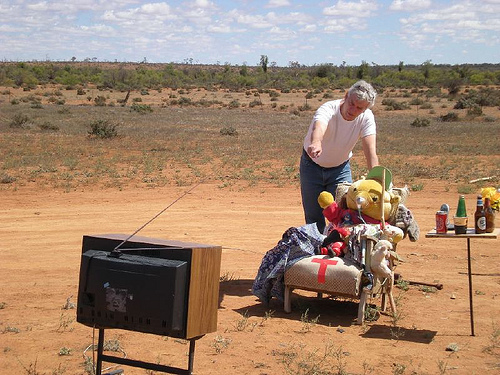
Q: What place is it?
A: It is a desert.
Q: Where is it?
A: This is at the desert.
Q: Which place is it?
A: It is a desert.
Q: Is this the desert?
A: Yes, it is the desert.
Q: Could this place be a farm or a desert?
A: It is a desert.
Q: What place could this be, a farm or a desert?
A: It is a desert.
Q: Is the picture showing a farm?
A: No, the picture is showing a desert.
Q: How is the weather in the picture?
A: It is clear.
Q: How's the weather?
A: It is clear.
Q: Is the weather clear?
A: Yes, it is clear.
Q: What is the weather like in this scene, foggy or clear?
A: It is clear.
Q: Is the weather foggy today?
A: No, it is clear.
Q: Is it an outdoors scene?
A: Yes, it is outdoors.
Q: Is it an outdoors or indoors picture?
A: It is outdoors.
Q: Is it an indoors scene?
A: No, it is outdoors.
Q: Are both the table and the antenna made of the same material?
A: No, the table is made of wood and the antenna is made of metal.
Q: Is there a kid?
A: No, there are no children.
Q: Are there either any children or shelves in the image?
A: No, there are no children or shelves.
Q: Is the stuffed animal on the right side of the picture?
A: Yes, the stuffed animal is on the right of the image.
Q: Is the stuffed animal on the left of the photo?
A: No, the stuffed animal is on the right of the image.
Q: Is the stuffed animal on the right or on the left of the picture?
A: The stuffed animal is on the right of the image.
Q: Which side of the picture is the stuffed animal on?
A: The stuffed animal is on the right of the image.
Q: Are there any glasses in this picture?
A: No, there are no glasses.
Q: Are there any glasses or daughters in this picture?
A: No, there are no glasses or daughters.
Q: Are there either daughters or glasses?
A: No, there are no glasses or daughters.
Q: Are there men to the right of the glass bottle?
A: No, the man is to the left of the bottle.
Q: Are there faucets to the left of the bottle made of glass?
A: No, there is a man to the left of the bottle.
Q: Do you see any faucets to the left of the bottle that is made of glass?
A: No, there is a man to the left of the bottle.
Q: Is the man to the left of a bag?
A: No, the man is to the left of the bottle.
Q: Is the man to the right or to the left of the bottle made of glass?
A: The man is to the left of the bottle.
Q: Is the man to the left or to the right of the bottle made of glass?
A: The man is to the left of the bottle.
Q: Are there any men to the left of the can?
A: Yes, there is a man to the left of the can.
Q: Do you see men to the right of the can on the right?
A: No, the man is to the left of the can.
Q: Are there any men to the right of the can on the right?
A: No, the man is to the left of the can.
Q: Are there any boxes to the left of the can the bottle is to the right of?
A: No, there is a man to the left of the can.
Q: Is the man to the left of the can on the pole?
A: Yes, the man is to the left of the can.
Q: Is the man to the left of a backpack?
A: No, the man is to the left of the can.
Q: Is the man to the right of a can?
A: No, the man is to the left of a can.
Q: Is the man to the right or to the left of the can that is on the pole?
A: The man is to the left of the can.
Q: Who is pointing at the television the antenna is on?
A: The man is pointing at the TV.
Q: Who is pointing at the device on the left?
A: The man is pointing at the TV.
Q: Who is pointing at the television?
A: The man is pointing at the TV.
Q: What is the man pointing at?
A: The man is pointing at the television.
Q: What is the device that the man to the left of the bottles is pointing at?
A: The device is a television.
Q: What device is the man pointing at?
A: The man is pointing at the TV.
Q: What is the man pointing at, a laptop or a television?
A: The man is pointing at a television.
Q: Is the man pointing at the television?
A: Yes, the man is pointing at the television.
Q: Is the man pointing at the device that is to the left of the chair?
A: Yes, the man is pointing at the television.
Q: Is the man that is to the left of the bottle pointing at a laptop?
A: No, the man is pointing at the television.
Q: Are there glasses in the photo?
A: No, there are no glasses.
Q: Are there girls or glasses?
A: No, there are no glasses or girls.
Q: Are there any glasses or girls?
A: No, there are no glasses or girls.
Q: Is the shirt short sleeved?
A: Yes, the shirt is short sleeved.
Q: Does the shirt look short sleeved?
A: Yes, the shirt is short sleeved.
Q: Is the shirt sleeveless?
A: No, the shirt is short sleeved.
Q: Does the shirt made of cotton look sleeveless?
A: No, the shirt is short sleeved.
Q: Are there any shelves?
A: No, there are no shelves.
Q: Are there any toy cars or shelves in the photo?
A: No, there are no shelves or toy cars.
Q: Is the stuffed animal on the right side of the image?
A: Yes, the stuffed animal is on the right of the image.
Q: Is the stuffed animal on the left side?
A: No, the stuffed animal is on the right of the image.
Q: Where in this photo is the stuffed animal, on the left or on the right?
A: The stuffed animal is on the right of the image.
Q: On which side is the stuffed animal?
A: The stuffed animal is on the right of the image.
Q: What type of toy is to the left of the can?
A: The toy is a stuffed animal.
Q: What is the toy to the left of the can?
A: The toy is a stuffed animal.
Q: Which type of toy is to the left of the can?
A: The toy is a stuffed animal.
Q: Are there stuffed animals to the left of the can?
A: Yes, there is a stuffed animal to the left of the can.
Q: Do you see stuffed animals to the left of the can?
A: Yes, there is a stuffed animal to the left of the can.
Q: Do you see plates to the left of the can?
A: No, there is a stuffed animal to the left of the can.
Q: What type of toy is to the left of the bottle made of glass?
A: The toy is a stuffed animal.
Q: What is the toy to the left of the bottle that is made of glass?
A: The toy is a stuffed animal.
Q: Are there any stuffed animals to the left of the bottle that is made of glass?
A: Yes, there is a stuffed animal to the left of the bottle.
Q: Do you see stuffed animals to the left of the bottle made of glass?
A: Yes, there is a stuffed animal to the left of the bottle.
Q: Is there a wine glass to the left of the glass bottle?
A: No, there is a stuffed animal to the left of the bottle.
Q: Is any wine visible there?
A: No, there is no wine.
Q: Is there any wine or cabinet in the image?
A: No, there are no wine or cabinets.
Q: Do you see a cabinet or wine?
A: No, there are no wine or cabinets.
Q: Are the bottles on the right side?
A: Yes, the bottles are on the right of the image.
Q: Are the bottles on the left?
A: No, the bottles are on the right of the image.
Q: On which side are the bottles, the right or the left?
A: The bottles are on the right of the image.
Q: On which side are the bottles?
A: The bottles are on the right of the image.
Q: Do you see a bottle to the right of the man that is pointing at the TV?
A: Yes, there are bottles to the right of the man.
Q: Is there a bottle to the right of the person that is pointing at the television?
A: Yes, there are bottles to the right of the man.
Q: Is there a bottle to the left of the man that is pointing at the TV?
A: No, the bottles are to the right of the man.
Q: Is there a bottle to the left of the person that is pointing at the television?
A: No, the bottles are to the right of the man.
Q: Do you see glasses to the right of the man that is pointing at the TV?
A: No, there are bottles to the right of the man.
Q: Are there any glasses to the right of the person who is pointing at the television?
A: No, there are bottles to the right of the man.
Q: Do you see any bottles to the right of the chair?
A: Yes, there are bottles to the right of the chair.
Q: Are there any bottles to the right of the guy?
A: Yes, there are bottles to the right of the guy.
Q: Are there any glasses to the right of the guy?
A: No, there are bottles to the right of the guy.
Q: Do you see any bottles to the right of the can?
A: Yes, there are bottles to the right of the can.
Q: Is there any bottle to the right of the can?
A: Yes, there are bottles to the right of the can.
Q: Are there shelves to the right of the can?
A: No, there are bottles to the right of the can.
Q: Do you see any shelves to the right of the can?
A: No, there are bottles to the right of the can.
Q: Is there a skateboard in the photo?
A: No, there are no skateboards.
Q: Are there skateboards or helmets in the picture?
A: No, there are no skateboards or helmets.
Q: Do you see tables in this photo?
A: Yes, there is a table.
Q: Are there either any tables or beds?
A: Yes, there is a table.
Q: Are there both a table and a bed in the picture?
A: No, there is a table but no beds.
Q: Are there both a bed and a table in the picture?
A: No, there is a table but no beds.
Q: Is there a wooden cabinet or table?
A: Yes, there is a wood table.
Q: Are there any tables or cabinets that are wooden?
A: Yes, the table is wooden.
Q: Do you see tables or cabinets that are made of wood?
A: Yes, the table is made of wood.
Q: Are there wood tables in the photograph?
A: Yes, there is a wood table.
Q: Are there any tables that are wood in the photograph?
A: Yes, there is a wood table.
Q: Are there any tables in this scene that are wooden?
A: Yes, there is a table that is wooden.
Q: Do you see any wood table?
A: Yes, there is a table that is made of wood.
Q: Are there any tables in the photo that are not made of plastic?
A: Yes, there is a table that is made of wood.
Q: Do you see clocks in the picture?
A: No, there are no clocks.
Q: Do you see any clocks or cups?
A: No, there are no clocks or cups.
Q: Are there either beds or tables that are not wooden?
A: No, there is a table but it is wooden.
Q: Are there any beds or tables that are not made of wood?
A: No, there is a table but it is made of wood.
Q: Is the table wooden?
A: Yes, the table is wooden.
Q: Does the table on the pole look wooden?
A: Yes, the table is wooden.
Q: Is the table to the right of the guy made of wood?
A: Yes, the table is made of wood.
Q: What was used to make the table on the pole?
A: The table is made of wood.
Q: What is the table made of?
A: The table is made of wood.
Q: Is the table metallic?
A: No, the table is wooden.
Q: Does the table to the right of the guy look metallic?
A: No, the table is wooden.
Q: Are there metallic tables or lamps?
A: No, there is a table but it is wooden.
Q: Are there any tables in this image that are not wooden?
A: No, there is a table but it is wooden.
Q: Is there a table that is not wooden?
A: No, there is a table but it is wooden.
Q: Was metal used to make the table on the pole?
A: No, the table is made of wood.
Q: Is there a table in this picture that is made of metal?
A: No, there is a table but it is made of wood.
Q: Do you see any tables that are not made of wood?
A: No, there is a table but it is made of wood.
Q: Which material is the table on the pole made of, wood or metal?
A: The table is made of wood.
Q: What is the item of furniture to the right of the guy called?
A: The piece of furniture is a table.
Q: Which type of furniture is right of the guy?
A: The piece of furniture is a table.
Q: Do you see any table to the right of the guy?
A: Yes, there is a table to the right of the guy.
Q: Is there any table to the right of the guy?
A: Yes, there is a table to the right of the guy.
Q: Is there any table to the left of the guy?
A: No, the table is to the right of the guy.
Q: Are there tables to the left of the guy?
A: No, the table is to the right of the guy.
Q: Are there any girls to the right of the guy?
A: No, there is a table to the right of the guy.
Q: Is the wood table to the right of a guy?
A: Yes, the table is to the right of a guy.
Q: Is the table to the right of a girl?
A: No, the table is to the right of a guy.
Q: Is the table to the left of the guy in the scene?
A: No, the table is to the right of the guy.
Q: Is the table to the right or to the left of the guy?
A: The table is to the right of the guy.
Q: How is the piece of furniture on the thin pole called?
A: The piece of furniture is a table.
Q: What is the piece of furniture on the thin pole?
A: The piece of furniture is a table.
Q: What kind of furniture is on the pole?
A: The piece of furniture is a table.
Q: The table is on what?
A: The table is on the pole.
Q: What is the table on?
A: The table is on the pole.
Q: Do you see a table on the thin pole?
A: Yes, there is a table on the pole.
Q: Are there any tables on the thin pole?
A: Yes, there is a table on the pole.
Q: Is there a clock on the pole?
A: No, there is a table on the pole.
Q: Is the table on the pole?
A: Yes, the table is on the pole.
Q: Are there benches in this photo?
A: No, there are no benches.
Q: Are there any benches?
A: No, there are no benches.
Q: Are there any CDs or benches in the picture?
A: No, there are no benches or cds.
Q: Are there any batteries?
A: No, there are no batteries.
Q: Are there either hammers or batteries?
A: No, there are no batteries or hammers.